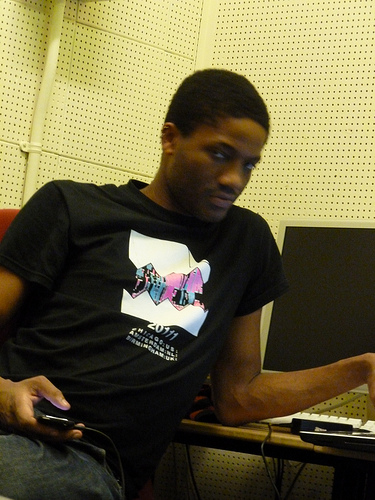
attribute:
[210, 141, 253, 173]
eyes — suspicious, following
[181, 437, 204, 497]
cords — hanging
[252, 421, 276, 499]
cords — hanging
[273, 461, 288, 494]
cords — hanging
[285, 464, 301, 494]
cords — hanging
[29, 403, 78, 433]
phone — on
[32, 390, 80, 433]
phone — lit up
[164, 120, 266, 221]
face — young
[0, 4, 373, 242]
white pegboard — enclosed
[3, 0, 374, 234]
divider — perforated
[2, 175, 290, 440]
tee shirt — black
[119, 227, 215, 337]
design — white, purple, blue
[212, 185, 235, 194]
mustache — little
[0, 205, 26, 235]
chair — red, office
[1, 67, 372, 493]
man — holding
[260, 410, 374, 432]
keyboard — white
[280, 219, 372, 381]
screen — off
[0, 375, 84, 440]
hand — holding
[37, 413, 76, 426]
device — charding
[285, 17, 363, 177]
holes — zilllion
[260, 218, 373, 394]
monitor — Large 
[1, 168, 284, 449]
shirt — black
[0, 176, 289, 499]
shirt — black